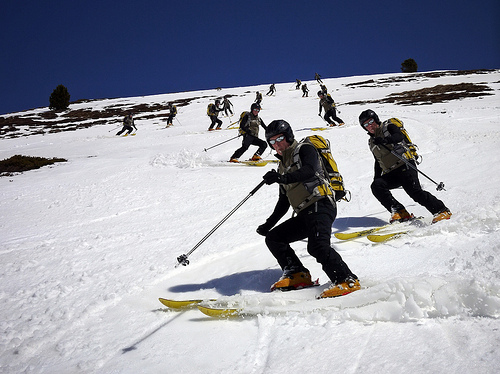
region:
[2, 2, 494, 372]
A group of people are skiing down the hill.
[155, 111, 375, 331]
One person on the ski slope.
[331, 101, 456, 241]
A second person on the ski slope.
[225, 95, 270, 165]
A third person on the ski slope.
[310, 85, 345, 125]
A fourth person on the ski slope.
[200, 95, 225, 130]
A fifth person on the ski slope.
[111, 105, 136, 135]
A sixth person on the ski slope.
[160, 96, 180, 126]
A seventh person on the ski slope.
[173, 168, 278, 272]
The man is holding a ski pole.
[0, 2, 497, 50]
The sky is blue.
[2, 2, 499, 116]
the clear blue sky above the mountain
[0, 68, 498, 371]
the snow on the mountain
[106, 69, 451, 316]
the group of people skiing down the mountain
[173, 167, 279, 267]
the ski pole in the man's hand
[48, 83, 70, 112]
the tree on the mountain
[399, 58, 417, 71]
the tree on the mountain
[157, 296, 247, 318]
the front of the yellow skis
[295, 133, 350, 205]
the backpack on the man's back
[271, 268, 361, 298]
the ski boots on the man's feet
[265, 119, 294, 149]
the helmet on the man's head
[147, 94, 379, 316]
person who is skiing.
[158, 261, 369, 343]
Skis in the snow.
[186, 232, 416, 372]
Snow on the ground.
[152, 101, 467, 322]
Person holding a ski pole.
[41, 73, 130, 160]
Tree in the background.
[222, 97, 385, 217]
Helmet on the man.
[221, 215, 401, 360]
Snow boots on the man.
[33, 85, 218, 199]
Dirt showing through the snow.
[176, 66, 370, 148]
People in the background.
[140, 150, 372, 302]
Silver ski pole.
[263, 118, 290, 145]
the skier is wearing a helmet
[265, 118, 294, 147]
the helmet is black in color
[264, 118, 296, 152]
the helmet is shiny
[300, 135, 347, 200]
the skier is wearing a backpack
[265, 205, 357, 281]
the skier is wearing long pants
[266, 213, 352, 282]
the pants are black in color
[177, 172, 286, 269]
the skier is holding a ski pole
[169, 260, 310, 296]
a shadow is on the snow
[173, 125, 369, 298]
the skier is casting a shadow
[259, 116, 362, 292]
the skier is at an angle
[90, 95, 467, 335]
Men are skiing down a hill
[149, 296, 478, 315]
Men are wearing yellow skis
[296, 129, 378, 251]
The man is wearing a yellow backpack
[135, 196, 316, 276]
The man has a ski pole in his head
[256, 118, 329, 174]
The man is wearing a helmet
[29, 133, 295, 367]
Snow is covering the hill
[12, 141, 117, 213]
Melted snow reveals grass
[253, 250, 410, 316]
The man is wearing ski shoes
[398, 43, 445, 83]
Trees are in the background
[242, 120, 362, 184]
Ski glasses are on the man's face